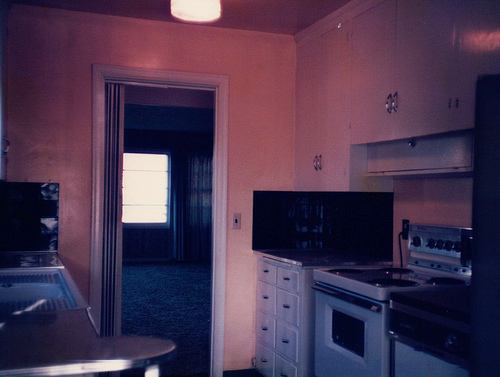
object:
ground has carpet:
[121, 264, 210, 376]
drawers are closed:
[255, 255, 304, 376]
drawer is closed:
[275, 267, 299, 294]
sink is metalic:
[0, 258, 177, 373]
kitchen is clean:
[0, 2, 497, 376]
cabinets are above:
[292, 17, 358, 191]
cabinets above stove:
[347, 0, 480, 147]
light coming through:
[121, 152, 167, 224]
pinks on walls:
[0, 1, 296, 372]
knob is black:
[412, 237, 421, 247]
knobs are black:
[411, 236, 462, 252]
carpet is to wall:
[121, 260, 210, 375]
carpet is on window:
[169, 139, 210, 263]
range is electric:
[314, 268, 472, 376]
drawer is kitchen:
[256, 258, 277, 284]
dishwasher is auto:
[389, 298, 472, 364]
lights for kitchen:
[170, 0, 221, 23]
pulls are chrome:
[385, 92, 393, 113]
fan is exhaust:
[365, 135, 473, 175]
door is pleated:
[104, 84, 120, 336]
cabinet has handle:
[382, 90, 398, 113]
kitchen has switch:
[231, 213, 241, 230]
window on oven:
[331, 308, 365, 360]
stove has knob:
[436, 239, 443, 250]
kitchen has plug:
[401, 219, 409, 239]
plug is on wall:
[401, 218, 410, 239]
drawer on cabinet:
[275, 288, 300, 325]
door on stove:
[315, 280, 389, 373]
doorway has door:
[92, 64, 224, 376]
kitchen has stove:
[311, 266, 473, 300]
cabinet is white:
[293, 5, 350, 192]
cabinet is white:
[353, 5, 442, 140]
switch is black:
[235, 219, 238, 224]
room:
[4, 5, 498, 375]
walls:
[300, 11, 400, 96]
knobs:
[453, 241, 463, 253]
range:
[305, 260, 482, 373]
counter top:
[250, 248, 397, 272]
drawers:
[273, 322, 298, 368]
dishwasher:
[375, 286, 500, 369]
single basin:
[0, 261, 91, 325]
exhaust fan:
[362, 133, 470, 177]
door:
[108, 79, 125, 349]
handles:
[389, 90, 400, 111]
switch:
[227, 212, 243, 236]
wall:
[0, 0, 305, 374]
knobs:
[426, 237, 436, 248]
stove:
[308, 251, 477, 374]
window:
[119, 149, 170, 227]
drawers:
[252, 342, 275, 374]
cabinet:
[248, 263, 313, 375]